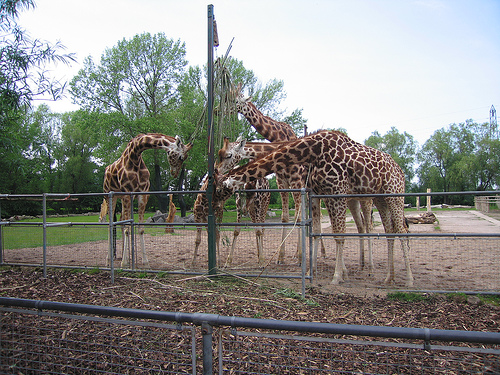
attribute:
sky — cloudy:
[294, 5, 496, 112]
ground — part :
[1, 265, 497, 373]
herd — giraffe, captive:
[92, 76, 417, 288]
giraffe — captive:
[207, 127, 414, 295]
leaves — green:
[66, 30, 203, 105]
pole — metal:
[217, 0, 224, 272]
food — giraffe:
[211, 81, 226, 122]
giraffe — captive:
[93, 130, 195, 269]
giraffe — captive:
[212, 85, 305, 267]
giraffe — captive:
[212, 135, 378, 272]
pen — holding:
[4, 177, 498, 298]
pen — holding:
[3, 166, 499, 368]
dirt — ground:
[2, 200, 496, 296]